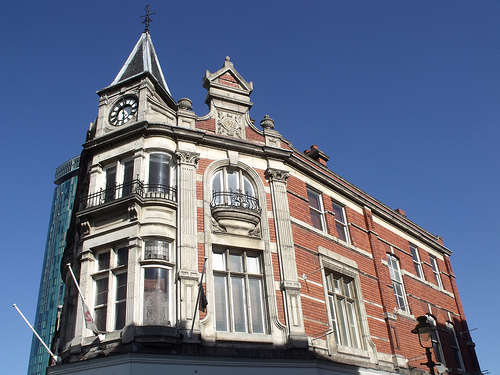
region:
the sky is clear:
[9, 36, 79, 128]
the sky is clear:
[264, 10, 358, 77]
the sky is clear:
[326, 58, 411, 138]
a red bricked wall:
[273, 225, 329, 265]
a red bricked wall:
[344, 242, 392, 329]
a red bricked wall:
[352, 212, 408, 259]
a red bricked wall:
[364, 266, 438, 366]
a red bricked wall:
[285, 196, 359, 263]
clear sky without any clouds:
[312, 21, 433, 150]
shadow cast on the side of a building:
[418, 281, 478, 374]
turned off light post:
[409, 313, 444, 374]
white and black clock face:
[104, 93, 144, 131]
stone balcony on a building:
[210, 174, 264, 241]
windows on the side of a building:
[211, 250, 268, 334]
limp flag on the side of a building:
[190, 251, 220, 328]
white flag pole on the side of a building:
[58, 258, 103, 345]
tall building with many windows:
[47, 182, 67, 324]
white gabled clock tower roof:
[114, 16, 169, 96]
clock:
[92, 94, 143, 135]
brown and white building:
[88, 30, 435, 374]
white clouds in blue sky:
[43, 18, 80, 88]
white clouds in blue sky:
[16, 75, 53, 120]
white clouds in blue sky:
[7, 161, 38, 203]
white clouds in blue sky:
[162, 9, 195, 51]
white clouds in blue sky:
[287, 22, 342, 94]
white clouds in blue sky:
[347, 30, 395, 99]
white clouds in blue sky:
[329, 98, 386, 150]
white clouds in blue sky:
[396, 32, 466, 87]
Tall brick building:
[28, 4, 483, 374]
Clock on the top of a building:
[104, 90, 141, 127]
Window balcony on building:
[207, 156, 264, 237]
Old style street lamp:
[408, 313, 443, 371]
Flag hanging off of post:
[181, 254, 211, 337]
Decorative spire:
[139, 3, 155, 35]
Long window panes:
[212, 244, 272, 335]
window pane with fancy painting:
[142, 264, 169, 327]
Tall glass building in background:
[28, 184, 75, 369]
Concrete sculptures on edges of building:
[176, 95, 196, 116]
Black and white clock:
[104, 96, 146, 131]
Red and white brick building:
[185, 125, 472, 374]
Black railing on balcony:
[74, 175, 183, 218]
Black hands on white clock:
[103, 92, 147, 132]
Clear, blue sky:
[4, 3, 499, 244]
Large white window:
[78, 228, 150, 340]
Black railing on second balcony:
[207, 188, 277, 245]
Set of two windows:
[303, 184, 368, 244]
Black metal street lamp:
[403, 314, 443, 374]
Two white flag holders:
[4, 246, 109, 362]